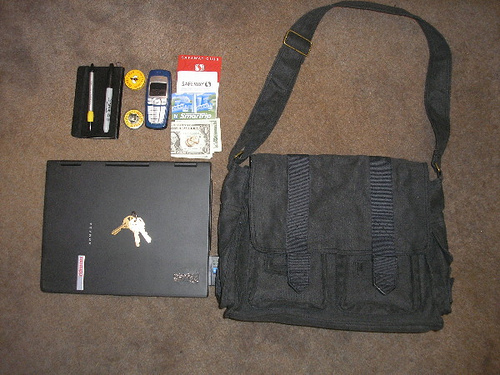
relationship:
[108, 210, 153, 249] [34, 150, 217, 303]
keys on laptop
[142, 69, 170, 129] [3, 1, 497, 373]
cell phone on floor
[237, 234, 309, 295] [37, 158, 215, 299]
pocket on laptop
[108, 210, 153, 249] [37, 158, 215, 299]
keys on laptop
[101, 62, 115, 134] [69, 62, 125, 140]
sharpie in checkbook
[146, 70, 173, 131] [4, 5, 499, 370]
cell phone on carpet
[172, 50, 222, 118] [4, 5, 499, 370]
ticket on carpet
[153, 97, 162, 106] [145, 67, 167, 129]
botton on phone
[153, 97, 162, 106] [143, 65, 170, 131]
botton on cell phone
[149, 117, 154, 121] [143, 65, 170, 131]
botton on cell phone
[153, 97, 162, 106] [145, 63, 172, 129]
botton on cell phone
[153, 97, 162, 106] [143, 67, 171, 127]
botton on cell phone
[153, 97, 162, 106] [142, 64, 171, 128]
botton on phone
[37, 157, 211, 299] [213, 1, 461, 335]
laptop near black bag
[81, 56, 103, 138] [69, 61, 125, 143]
pen on checkbook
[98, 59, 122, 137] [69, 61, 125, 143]
marker on checkbook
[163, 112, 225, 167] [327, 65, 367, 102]
money laying on carpet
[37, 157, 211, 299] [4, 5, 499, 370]
laptop on carpet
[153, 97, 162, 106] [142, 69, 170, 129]
botton on cell phone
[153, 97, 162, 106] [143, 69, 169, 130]
botton on cellphone